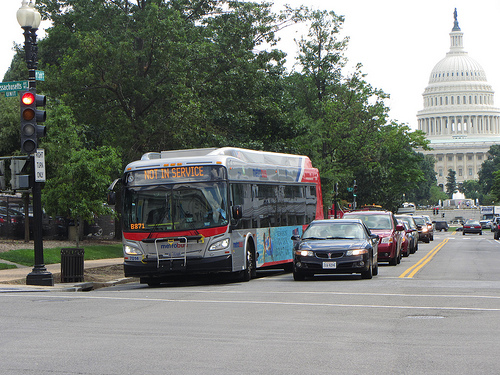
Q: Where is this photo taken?
A: On a street.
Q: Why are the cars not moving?
A: Because the light is red.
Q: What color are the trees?
A: Green.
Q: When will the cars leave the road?
A: When the light turns green.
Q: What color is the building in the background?
A: White.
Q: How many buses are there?
A: One.